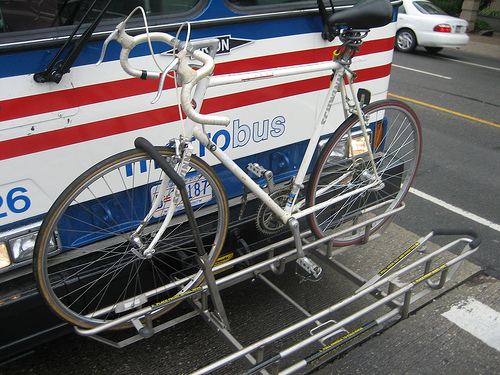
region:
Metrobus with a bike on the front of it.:
[116, 113, 277, 174]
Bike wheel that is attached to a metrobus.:
[101, 123, 272, 323]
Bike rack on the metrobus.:
[185, 229, 493, 316]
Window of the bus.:
[18, 0, 69, 30]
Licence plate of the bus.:
[143, 180, 239, 212]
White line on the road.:
[445, 300, 495, 368]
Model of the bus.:
[168, 30, 265, 64]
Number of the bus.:
[1, 180, 37, 229]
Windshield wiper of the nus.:
[55, 3, 115, 83]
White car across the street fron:
[403, 9, 454, 56]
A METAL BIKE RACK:
[94, 151, 498, 369]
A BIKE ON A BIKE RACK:
[27, 1, 482, 346]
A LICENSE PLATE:
[134, 165, 235, 215]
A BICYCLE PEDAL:
[286, 251, 329, 292]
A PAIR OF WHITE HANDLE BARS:
[86, 17, 259, 134]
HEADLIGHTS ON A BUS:
[271, 126, 422, 176]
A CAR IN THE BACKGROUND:
[396, 1, 471, 56]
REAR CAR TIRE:
[386, 22, 428, 57]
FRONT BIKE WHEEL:
[12, 146, 248, 341]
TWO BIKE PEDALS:
[226, 148, 337, 289]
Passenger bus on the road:
[2, 2, 412, 309]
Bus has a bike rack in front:
[27, 170, 485, 370]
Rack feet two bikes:
[41, 200, 496, 373]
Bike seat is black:
[301, 0, 411, 47]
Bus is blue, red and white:
[5, 6, 425, 294]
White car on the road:
[396, 3, 475, 59]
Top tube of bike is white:
[213, 65, 337, 88]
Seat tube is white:
[293, 57, 345, 202]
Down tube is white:
[203, 130, 288, 217]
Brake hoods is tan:
[72, 3, 157, 74]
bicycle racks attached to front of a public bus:
[38, 117, 456, 350]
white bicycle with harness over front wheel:
[21, 16, 427, 316]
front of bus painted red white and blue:
[31, 35, 372, 247]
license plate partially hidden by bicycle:
[136, 161, 226, 221]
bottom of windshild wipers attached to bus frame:
[25, 10, 365, 95]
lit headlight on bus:
[340, 125, 375, 160]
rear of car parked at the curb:
[395, 5, 470, 60]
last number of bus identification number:
[0, 176, 35, 216]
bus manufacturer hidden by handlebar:
[145, 31, 260, 61]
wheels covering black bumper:
[30, 135, 435, 336]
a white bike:
[21, 0, 429, 340]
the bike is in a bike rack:
[35, 0, 493, 374]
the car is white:
[392, 0, 480, 60]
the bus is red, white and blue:
[0, 0, 420, 372]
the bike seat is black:
[302, 0, 411, 35]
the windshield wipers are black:
[22, 0, 347, 92]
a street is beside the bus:
[356, 35, 497, 275]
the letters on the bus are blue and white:
[112, 110, 289, 178]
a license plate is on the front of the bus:
[143, 167, 217, 223]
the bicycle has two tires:
[26, 88, 429, 342]